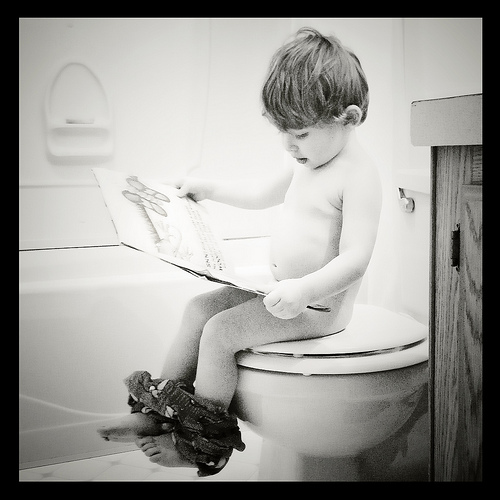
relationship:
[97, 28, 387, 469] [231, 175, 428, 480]
boy sits on toilet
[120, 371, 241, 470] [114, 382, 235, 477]
pajama pants near feet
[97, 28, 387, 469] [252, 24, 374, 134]
boy has hair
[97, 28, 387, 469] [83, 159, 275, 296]
boy reads book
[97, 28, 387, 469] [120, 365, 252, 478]
boy wears pants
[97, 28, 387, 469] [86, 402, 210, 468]
boy has feet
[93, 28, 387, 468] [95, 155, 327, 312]
boy reading book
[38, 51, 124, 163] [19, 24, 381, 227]
container on wall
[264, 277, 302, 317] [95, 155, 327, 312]
hand holding book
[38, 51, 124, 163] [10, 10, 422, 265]
container on wall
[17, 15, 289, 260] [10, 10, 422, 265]
shower has wall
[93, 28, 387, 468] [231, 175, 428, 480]
boy sitting on toilet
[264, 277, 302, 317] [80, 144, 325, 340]
hand holding book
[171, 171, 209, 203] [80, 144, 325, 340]
hand holding book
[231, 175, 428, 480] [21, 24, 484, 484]
toilet in bathroom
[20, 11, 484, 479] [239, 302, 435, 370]
toilet has lid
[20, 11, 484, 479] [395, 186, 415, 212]
toilet has handle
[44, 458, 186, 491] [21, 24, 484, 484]
floor in bathroom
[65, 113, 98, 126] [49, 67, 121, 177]
soap bar in tub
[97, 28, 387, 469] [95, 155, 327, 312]
boy holding book